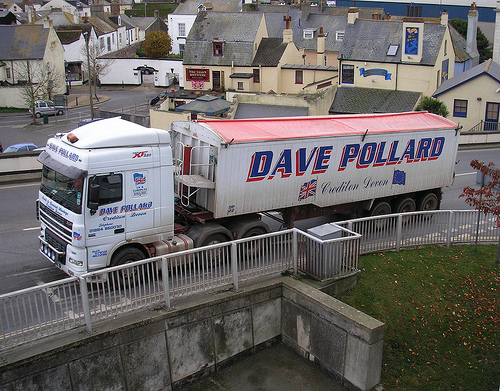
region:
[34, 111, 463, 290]
A blue white and red truck.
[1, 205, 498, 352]
White metal railing.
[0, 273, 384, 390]
Cement retaining wall.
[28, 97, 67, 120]
A gray vehicle.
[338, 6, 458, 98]
A building with blue signs.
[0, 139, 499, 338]
A gray paved road.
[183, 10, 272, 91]
A building with a red sign.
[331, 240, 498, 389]
Green grass with leaves on it.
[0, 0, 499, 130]
A large group of buildings.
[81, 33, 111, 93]
A brown dormant tree.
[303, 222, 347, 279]
trash can on the side of street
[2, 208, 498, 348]
fence surround the side of the street for safety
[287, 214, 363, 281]
fence was built so trash bin will remain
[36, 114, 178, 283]
cab of truck is white with blue lettering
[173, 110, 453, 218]
back of truck is white with red and blue lettering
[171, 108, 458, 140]
top of truck is a rolled canvas/plastic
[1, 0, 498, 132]
large area with houses/buildings cluttered together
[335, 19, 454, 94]
blue banner outside building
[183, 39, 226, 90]
red banner outside building with red window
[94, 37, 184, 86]
fenced in outside courtyard with white brick wall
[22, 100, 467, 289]
large truck on street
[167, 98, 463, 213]
truck is white with red roof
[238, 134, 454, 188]
truck has blue writing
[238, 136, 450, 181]
blue writing has red trim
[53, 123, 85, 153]
red light on top of truck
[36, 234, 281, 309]
street rail is light grey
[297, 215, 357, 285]
transformer box is light grey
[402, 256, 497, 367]
brown leafs on ground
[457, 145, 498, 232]
leaves on tree are brown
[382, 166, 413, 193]
tree has blue flag painted on side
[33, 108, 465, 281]
large red white and blue truck on over pass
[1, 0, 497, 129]
houses behind the truck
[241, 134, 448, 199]
logo on large truck back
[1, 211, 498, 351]
white fence on the road next to trunk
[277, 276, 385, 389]
concrete slan next to grass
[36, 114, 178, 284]
front cab of lage truck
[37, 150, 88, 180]
sun visor on the cab front window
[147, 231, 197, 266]
gas tank of large truck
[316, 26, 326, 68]
smoke stack of house in background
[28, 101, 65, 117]
grey car on the road behind truck